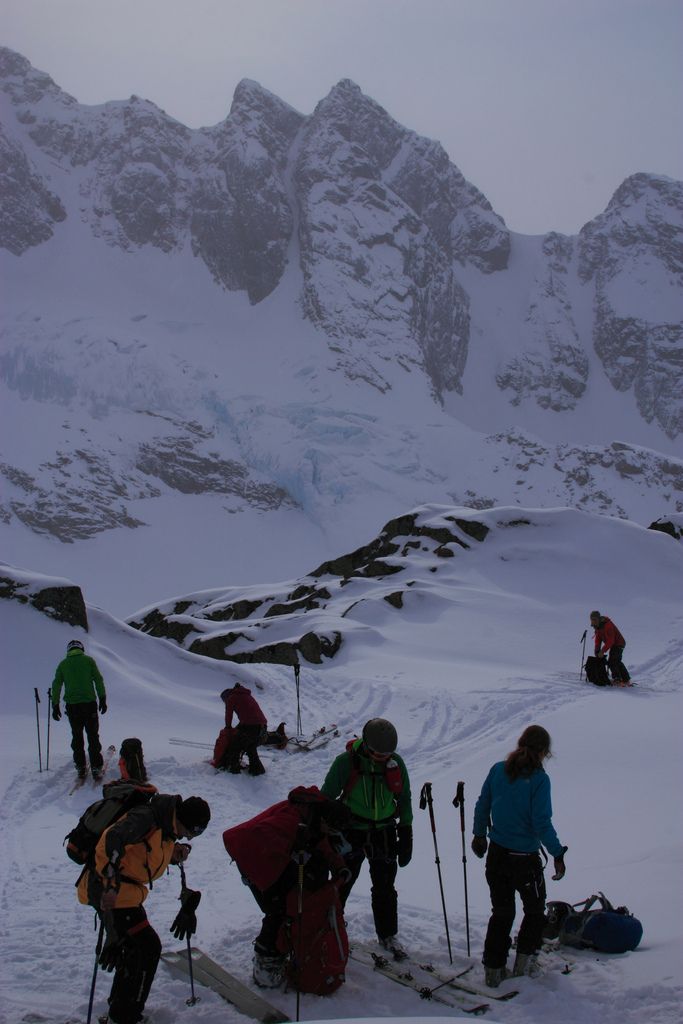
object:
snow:
[0, 47, 683, 512]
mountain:
[0, 0, 683, 1021]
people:
[45, 608, 636, 1024]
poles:
[34, 685, 51, 772]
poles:
[418, 781, 471, 965]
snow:
[0, 0, 683, 1024]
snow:
[399, 668, 587, 772]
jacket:
[60, 792, 180, 913]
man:
[61, 739, 211, 1023]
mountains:
[0, 46, 683, 462]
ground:
[0, 432, 683, 1024]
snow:
[0, 509, 683, 1024]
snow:
[0, 410, 303, 545]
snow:
[0, 469, 683, 1024]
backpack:
[62, 777, 159, 865]